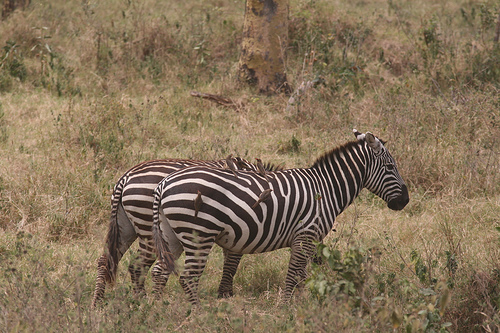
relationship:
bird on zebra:
[242, 189, 279, 210] [154, 143, 429, 291]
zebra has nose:
[154, 143, 429, 291] [402, 183, 409, 210]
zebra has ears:
[154, 143, 429, 291] [351, 129, 383, 146]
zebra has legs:
[154, 143, 429, 291] [144, 244, 336, 303]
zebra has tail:
[154, 143, 429, 291] [132, 194, 191, 270]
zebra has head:
[154, 143, 429, 291] [349, 135, 433, 233]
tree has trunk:
[235, 2, 317, 88] [206, 32, 307, 104]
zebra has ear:
[154, 143, 429, 291] [351, 129, 383, 146]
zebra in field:
[154, 143, 429, 291] [22, 17, 474, 132]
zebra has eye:
[154, 143, 429, 291] [378, 151, 406, 179]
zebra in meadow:
[154, 143, 429, 291] [17, 55, 479, 312]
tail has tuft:
[132, 194, 191, 270] [140, 237, 180, 266]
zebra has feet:
[154, 143, 429, 291] [270, 272, 349, 308]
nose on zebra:
[385, 180, 411, 210] [154, 143, 429, 291]